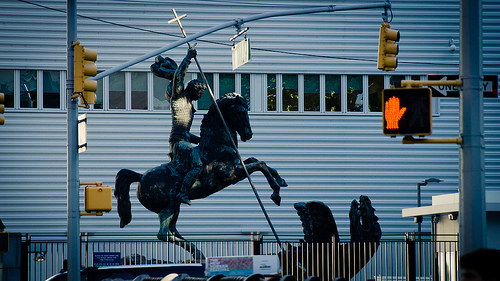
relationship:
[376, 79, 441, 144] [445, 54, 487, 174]
sign on pole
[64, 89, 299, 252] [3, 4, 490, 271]
horse on photo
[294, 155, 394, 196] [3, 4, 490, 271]
wall in photo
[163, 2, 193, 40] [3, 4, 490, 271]
cross in photo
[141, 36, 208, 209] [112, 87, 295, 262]
man riding horse